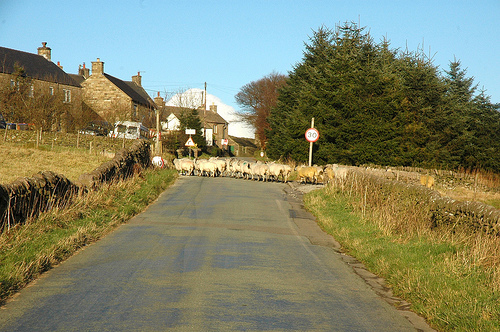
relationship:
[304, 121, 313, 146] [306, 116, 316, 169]
sign attached to pole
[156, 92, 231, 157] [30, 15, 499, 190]
house in distance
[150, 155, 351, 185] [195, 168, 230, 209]
animals crossing road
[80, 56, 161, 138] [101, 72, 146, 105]
brick building with roof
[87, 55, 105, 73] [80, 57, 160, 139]
chimney on brick building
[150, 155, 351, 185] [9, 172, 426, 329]
animals on a road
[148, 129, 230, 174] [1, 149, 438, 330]
signs on left side of road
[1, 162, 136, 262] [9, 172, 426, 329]
fence left side of road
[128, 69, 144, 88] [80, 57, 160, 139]
chimney on top of brick building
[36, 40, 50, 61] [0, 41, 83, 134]
chimney on top of building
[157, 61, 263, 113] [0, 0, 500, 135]
clouds in sky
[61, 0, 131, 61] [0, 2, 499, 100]
clouds in sky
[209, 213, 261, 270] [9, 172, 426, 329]
dirt on road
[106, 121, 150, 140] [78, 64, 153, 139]
bus parked in front of house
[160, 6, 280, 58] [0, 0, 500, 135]
clouds in sky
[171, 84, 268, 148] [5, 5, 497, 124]
clouds in sky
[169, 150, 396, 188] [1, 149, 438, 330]
animals crossing road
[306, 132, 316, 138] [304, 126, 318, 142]
30 on sign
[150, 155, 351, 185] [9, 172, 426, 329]
animals crossing road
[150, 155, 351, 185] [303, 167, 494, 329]
animals leaving field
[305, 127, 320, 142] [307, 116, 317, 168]
sign on pole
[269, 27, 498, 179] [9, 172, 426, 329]
trees aside road